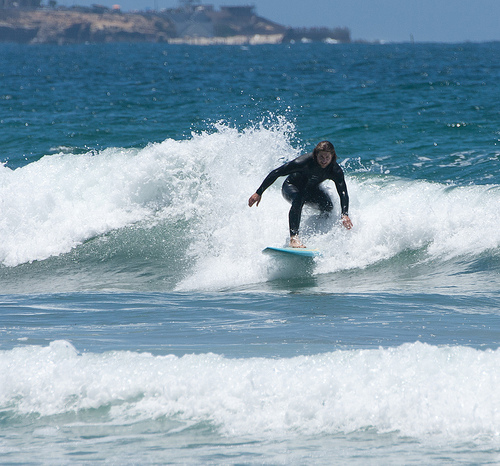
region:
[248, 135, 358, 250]
woman in black wet suit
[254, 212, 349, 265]
blue surfboard in ocean water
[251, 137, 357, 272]
woman in wet suit on surf board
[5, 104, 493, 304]
white wave on blue water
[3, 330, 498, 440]
white wave on blue water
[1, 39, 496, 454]
clear blue ocean water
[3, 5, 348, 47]
land formation in distance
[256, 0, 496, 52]
blue sunny cloudless sky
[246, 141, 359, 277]
woman crouching over blue surfboard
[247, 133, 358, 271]
woman on blue surfboard with blond hair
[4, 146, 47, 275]
This is a tide of water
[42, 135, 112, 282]
This is a tide of water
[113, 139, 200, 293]
This is a tide of water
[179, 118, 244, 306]
This is a tide of water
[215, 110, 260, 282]
This is a tide of water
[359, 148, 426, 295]
This is a tide of water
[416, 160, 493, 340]
This is a tide of water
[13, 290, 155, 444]
This is a tide of water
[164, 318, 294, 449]
This is a tide of water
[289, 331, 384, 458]
This is a tide of water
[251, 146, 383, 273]
a man riding a surfboard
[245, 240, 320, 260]
a blue surfboard in the water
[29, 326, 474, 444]
a wave rolling in towards the beach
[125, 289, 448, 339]
white ocean foam on the water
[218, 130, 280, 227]
white ocean spray from the surboard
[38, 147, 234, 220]
a cresting wave rolling over on itself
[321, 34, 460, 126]
calm blue waters behind the wave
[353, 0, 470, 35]
clear blue skies over the ocean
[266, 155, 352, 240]
the man's black wetsuit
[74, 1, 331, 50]
a hilly island in the distance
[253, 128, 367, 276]
the woman is surfing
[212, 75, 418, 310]
the woman is surfing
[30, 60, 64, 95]
the water is bluegreen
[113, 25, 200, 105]
the water is bluegreen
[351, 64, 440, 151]
the water is bluegreen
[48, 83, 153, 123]
the water is bluegreen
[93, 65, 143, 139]
the water is bluegreen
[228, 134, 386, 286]
a man riding on a surfboard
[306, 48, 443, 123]
calm blue waters of the ocean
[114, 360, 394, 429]
white ocean foam coming from a wave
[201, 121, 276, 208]
white ocean spray from the back of the surfboard